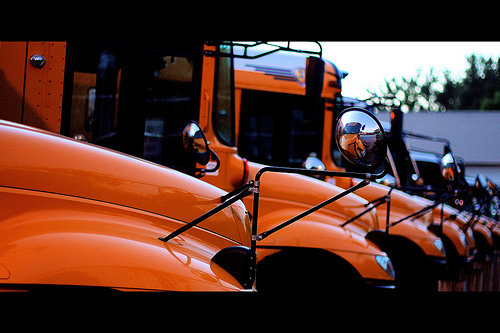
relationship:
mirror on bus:
[331, 103, 388, 171] [229, 38, 458, 293]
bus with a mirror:
[229, 38, 458, 293] [331, 103, 388, 171]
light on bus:
[374, 250, 401, 280] [229, 38, 458, 293]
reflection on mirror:
[337, 119, 368, 160] [331, 103, 388, 171]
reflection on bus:
[337, 119, 368, 160] [229, 38, 458, 293]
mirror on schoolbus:
[331, 103, 388, 171] [2, 102, 260, 293]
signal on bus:
[459, 230, 472, 251] [229, 38, 458, 293]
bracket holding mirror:
[153, 164, 391, 288] [331, 103, 388, 171]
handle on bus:
[202, 91, 211, 132] [229, 38, 458, 293]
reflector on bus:
[333, 65, 351, 81] [229, 38, 458, 293]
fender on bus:
[256, 214, 397, 290] [229, 38, 458, 293]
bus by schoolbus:
[229, 38, 458, 293] [2, 102, 260, 293]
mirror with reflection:
[331, 103, 388, 171] [337, 119, 368, 160]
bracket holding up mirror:
[153, 164, 391, 288] [331, 103, 388, 171]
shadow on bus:
[268, 186, 369, 231] [229, 38, 458, 293]